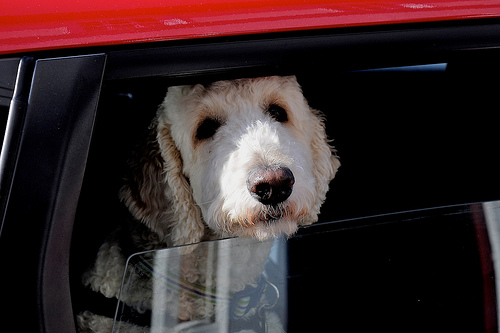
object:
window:
[67, 44, 499, 333]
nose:
[247, 167, 296, 205]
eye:
[194, 115, 223, 141]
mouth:
[248, 206, 295, 225]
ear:
[114, 108, 204, 255]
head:
[116, 75, 339, 254]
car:
[0, 0, 500, 333]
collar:
[119, 232, 279, 322]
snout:
[190, 144, 329, 241]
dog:
[76, 74, 339, 333]